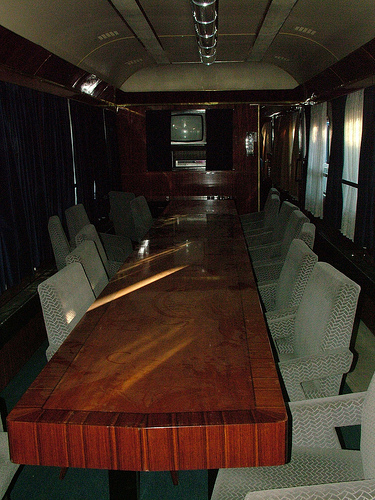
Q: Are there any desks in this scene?
A: Yes, there is a desk.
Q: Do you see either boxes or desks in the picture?
A: Yes, there is a desk.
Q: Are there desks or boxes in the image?
A: Yes, there is a desk.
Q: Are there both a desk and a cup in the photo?
A: No, there is a desk but no cups.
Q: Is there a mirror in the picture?
A: No, there are no mirrors.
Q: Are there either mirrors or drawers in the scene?
A: No, there are no mirrors or drawers.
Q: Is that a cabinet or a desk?
A: That is a desk.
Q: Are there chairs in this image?
A: Yes, there is a chair.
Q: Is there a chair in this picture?
A: Yes, there is a chair.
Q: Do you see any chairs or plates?
A: Yes, there is a chair.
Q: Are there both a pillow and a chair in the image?
A: No, there is a chair but no pillows.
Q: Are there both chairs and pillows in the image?
A: No, there is a chair but no pillows.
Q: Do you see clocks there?
A: No, there are no clocks.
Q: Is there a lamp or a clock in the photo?
A: No, there are no clocks or lamps.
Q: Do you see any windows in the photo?
A: Yes, there is a window.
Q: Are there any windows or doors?
A: Yes, there is a window.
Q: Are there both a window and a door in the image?
A: No, there is a window but no doors.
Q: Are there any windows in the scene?
A: Yes, there is a window.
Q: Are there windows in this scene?
A: Yes, there is a window.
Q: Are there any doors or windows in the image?
A: Yes, there is a window.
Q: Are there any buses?
A: No, there are no buses.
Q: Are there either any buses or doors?
A: No, there are no buses or doors.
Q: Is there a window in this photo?
A: Yes, there is a window.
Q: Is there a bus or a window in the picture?
A: Yes, there is a window.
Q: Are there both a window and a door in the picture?
A: No, there is a window but no doors.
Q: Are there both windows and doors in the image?
A: No, there is a window but no doors.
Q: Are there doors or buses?
A: No, there are no buses or doors.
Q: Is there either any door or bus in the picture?
A: No, there are no buses or doors.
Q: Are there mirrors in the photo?
A: No, there are no mirrors.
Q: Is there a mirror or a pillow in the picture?
A: No, there are no mirrors or pillows.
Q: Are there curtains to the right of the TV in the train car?
A: Yes, there are curtains to the right of the television.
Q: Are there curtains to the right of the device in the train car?
A: Yes, there are curtains to the right of the television.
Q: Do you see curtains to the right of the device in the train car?
A: Yes, there are curtains to the right of the television.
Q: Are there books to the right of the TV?
A: No, there are curtains to the right of the TV.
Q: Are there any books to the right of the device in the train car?
A: No, there are curtains to the right of the TV.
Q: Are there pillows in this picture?
A: No, there are no pillows.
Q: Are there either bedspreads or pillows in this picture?
A: No, there are no pillows or bedspreads.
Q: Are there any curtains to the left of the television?
A: Yes, there are curtains to the left of the television.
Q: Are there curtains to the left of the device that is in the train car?
A: Yes, there are curtains to the left of the television.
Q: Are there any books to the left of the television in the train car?
A: No, there are curtains to the left of the TV.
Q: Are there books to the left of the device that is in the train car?
A: No, there are curtains to the left of the TV.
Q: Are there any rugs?
A: No, there are no rugs.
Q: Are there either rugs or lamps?
A: No, there are no rugs or lamps.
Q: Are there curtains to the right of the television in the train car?
A: Yes, there are curtains to the right of the television.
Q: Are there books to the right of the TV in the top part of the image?
A: No, there are curtains to the right of the TV.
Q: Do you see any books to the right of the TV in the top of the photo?
A: No, there are curtains to the right of the TV.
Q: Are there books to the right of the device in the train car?
A: No, there are curtains to the right of the TV.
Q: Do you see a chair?
A: Yes, there is a chair.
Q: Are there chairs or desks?
A: Yes, there is a chair.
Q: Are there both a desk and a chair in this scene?
A: Yes, there are both a chair and a desk.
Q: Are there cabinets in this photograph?
A: No, there are no cabinets.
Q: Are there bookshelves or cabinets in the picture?
A: No, there are no cabinets or bookshelves.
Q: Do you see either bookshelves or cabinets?
A: No, there are no cabinets or bookshelves.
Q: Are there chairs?
A: Yes, there is a chair.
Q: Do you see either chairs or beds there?
A: Yes, there is a chair.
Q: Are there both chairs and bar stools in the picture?
A: No, there is a chair but no bar stools.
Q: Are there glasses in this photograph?
A: No, there are no glasses.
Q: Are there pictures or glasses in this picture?
A: No, there are no glasses or pictures.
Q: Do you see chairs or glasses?
A: Yes, there is a chair.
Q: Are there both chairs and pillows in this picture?
A: No, there is a chair but no pillows.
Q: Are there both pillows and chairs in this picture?
A: No, there is a chair but no pillows.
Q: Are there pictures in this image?
A: No, there are no pictures.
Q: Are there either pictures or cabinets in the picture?
A: No, there are no pictures or cabinets.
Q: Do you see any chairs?
A: Yes, there is a chair.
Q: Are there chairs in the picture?
A: Yes, there is a chair.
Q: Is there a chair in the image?
A: Yes, there is a chair.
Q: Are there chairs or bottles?
A: Yes, there is a chair.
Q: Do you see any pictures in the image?
A: No, there are no pictures.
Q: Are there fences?
A: No, there are no fences.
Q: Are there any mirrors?
A: No, there are no mirrors.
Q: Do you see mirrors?
A: No, there are no mirrors.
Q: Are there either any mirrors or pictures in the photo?
A: No, there are no mirrors or pictures.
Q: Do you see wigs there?
A: No, there are no wigs.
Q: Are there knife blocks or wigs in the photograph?
A: No, there are no wigs or knife blocks.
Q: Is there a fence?
A: No, there are no fences.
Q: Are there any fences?
A: No, there are no fences.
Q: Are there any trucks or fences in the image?
A: No, there are no fences or trucks.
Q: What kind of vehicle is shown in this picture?
A: The vehicle is a train car.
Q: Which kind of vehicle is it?
A: The vehicle is a train car.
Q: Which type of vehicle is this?
A: This is a train car.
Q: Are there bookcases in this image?
A: No, there are no bookcases.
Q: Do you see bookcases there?
A: No, there are no bookcases.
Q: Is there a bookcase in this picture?
A: No, there are no bookcases.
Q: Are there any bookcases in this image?
A: No, there are no bookcases.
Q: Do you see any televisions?
A: Yes, there is a television.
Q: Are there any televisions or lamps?
A: Yes, there is a television.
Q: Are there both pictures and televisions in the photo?
A: No, there is a television but no pictures.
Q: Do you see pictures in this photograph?
A: No, there are no pictures.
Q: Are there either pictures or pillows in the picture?
A: No, there are no pictures or pillows.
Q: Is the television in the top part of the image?
A: Yes, the television is in the top of the image.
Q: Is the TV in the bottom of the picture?
A: No, the TV is in the top of the image.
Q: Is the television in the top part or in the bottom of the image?
A: The television is in the top of the image.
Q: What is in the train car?
A: The TV is in the train car.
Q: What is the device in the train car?
A: The device is a television.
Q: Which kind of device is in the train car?
A: The device is a television.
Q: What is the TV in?
A: The TV is in the train car.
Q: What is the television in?
A: The TV is in the train car.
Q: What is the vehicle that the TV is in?
A: The vehicle is a train car.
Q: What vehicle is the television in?
A: The TV is in the train car.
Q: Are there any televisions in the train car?
A: Yes, there is a television in the train car.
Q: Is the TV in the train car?
A: Yes, the TV is in the train car.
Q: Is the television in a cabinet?
A: No, the television is in the train car.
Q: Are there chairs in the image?
A: Yes, there is a chair.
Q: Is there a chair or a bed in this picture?
A: Yes, there is a chair.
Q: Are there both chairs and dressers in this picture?
A: No, there is a chair but no dressers.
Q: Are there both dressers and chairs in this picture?
A: No, there is a chair but no dressers.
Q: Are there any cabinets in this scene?
A: No, there are no cabinets.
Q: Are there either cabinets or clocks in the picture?
A: No, there are no cabinets or clocks.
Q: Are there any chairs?
A: Yes, there is a chair.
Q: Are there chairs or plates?
A: Yes, there is a chair.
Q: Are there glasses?
A: No, there are no glasses.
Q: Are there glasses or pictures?
A: No, there are no glasses or pictures.